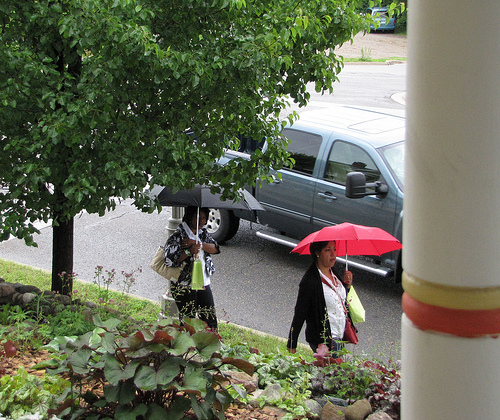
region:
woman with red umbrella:
[265, 210, 402, 362]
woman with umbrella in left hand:
[261, 212, 407, 374]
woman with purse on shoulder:
[280, 206, 405, 366]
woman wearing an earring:
[273, 210, 402, 368]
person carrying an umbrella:
[280, 216, 400, 367]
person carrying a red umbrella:
[270, 212, 398, 378]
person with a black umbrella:
[144, 165, 278, 332]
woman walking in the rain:
[263, 204, 408, 379]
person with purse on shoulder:
[125, 160, 268, 328]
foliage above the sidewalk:
[0, 294, 400, 419]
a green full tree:
[23, 33, 224, 183]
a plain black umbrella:
[163, 165, 291, 215]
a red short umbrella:
[303, 226, 406, 261]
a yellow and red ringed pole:
[400, 273, 488, 347]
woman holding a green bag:
[334, 289, 372, 316]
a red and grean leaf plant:
[98, 305, 253, 414]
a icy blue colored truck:
[214, 102, 431, 258]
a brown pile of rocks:
[295, 391, 387, 418]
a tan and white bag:
[144, 243, 184, 274]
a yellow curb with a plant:
[347, 48, 393, 70]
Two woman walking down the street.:
[150, 157, 377, 374]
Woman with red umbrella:
[281, 208, 395, 370]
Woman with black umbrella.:
[144, 175, 265, 327]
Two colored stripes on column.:
[396, 265, 496, 343]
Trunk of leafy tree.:
[50, 217, 75, 294]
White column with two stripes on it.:
[400, 2, 498, 417]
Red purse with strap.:
[312, 276, 357, 347]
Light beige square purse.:
[148, 245, 188, 283]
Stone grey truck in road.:
[181, 110, 404, 272]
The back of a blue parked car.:
[367, 5, 397, 32]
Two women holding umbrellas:
[140, 172, 404, 357]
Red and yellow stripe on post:
[396, 272, 498, 346]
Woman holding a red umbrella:
[284, 217, 397, 355]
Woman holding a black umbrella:
[138, 178, 258, 318]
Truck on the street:
[143, 105, 410, 284]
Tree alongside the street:
[4, 0, 368, 303]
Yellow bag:
[337, 283, 373, 323]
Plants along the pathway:
[0, 310, 402, 418]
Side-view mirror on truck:
[342, 168, 387, 206]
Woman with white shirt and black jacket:
[286, 235, 365, 353]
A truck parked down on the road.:
[147, 105, 402, 289]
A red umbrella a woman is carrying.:
[286, 219, 400, 260]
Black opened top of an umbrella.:
[138, 172, 264, 212]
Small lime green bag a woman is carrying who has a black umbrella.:
[188, 255, 208, 291]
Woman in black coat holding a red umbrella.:
[285, 233, 355, 365]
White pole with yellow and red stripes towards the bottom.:
[399, 0, 499, 417]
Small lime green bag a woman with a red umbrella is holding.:
[344, 281, 366, 324]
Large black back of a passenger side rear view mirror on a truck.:
[344, 172, 366, 197]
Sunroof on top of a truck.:
[345, 110, 405, 136]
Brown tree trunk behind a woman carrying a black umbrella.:
[45, 181, 77, 298]